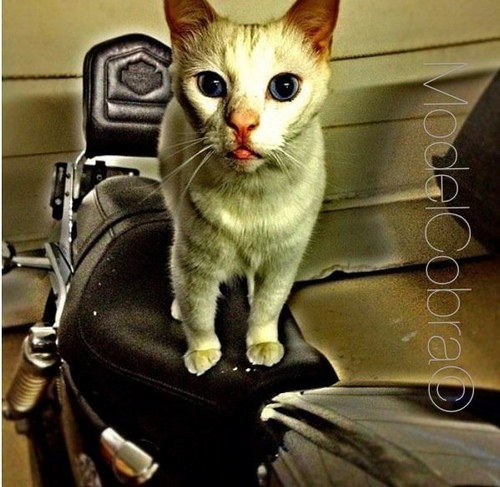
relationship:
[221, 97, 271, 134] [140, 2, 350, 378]
nose on cat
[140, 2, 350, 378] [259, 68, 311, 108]
cat has left eye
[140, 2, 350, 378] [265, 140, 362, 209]
cat has left side whiskers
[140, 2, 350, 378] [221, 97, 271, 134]
cat has nose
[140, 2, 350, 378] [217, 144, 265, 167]
cat has mouth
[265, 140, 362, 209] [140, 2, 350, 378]
left side whiskers are on cat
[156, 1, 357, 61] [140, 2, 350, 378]
ears are on cat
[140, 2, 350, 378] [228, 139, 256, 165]
cat sticking out tongue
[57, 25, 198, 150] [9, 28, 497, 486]
back of motorcycle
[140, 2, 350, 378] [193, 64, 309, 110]
cat has eyes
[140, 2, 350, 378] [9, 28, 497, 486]
cat on motorcycle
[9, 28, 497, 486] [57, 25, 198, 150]
motorcycle has back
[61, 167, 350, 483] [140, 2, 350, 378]
seat has cat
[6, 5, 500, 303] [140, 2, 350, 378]
wall behind cat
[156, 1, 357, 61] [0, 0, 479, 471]
ears in photograph